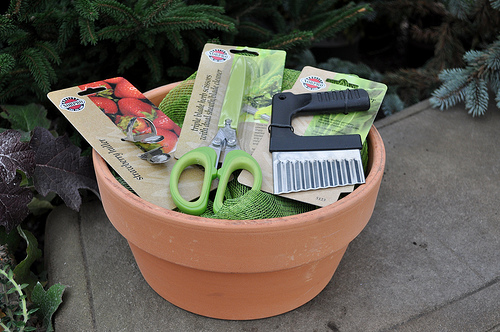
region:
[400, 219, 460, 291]
A gray concrete bench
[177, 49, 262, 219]
New green pruning shears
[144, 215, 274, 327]
A terracotta planter on bench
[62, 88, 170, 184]
A pack of strawberry seeds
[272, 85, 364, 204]
A black handled garden tool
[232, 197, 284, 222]
A piece of green garden mesh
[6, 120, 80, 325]
Purple and green plants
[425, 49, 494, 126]
A green plant branch on bench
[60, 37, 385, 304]
A pot full of gardening tools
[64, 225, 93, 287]
Dark line on concrete bench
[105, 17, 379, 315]
pot filled with kitchen items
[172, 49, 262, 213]
brand new green scissors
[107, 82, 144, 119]
strawberries on cardboard packaging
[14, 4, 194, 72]
green pine trees behind pot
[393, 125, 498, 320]
grey cement bench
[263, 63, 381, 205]
kitchen tool with black handle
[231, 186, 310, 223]
green plastic netting in pot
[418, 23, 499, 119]
lighter green pine tree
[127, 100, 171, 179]
silver tool to help with strawberries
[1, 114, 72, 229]
large reddish leaves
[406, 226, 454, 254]
small spot on asphalt bench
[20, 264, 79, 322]
green leaf on side of bench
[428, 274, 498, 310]
line on asphalt bench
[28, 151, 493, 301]
large gray asphalt bench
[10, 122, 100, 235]
purple leaf with lines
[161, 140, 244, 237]
green handle of green scissors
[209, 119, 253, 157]
silver screws on scissors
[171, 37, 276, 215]
large green scissors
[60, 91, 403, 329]
red clay pot on bench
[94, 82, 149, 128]
picture of strawberry on cardboard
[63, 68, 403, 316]
red clay garden pot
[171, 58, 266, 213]
green scissors in their package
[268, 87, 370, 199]
black and silver garden tool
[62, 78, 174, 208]
new strawberry picking tool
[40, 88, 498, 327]
cement pad where clay pot is sitting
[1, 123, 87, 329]
plant on left lower side of painting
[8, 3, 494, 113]
pine branches in upper portion of picture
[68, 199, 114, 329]
seam in cement on left side of picture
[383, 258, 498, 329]
seam in lower right section of cement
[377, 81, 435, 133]
seam in upper right section of cement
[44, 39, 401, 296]
new gardening products in a terra cotta bowl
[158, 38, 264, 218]
scissors new in package for gardening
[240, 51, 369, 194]
scraper or vegetable cutter new in package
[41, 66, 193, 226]
strawberry huller - removes top from strawberries new in package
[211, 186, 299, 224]
green netting may contain flower bulbs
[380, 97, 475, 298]
cement style wall or sidewalk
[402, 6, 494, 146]
blue spruce pine branch on sdewakl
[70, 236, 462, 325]
bottom of terra cotta bowl on cement surface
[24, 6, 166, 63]
pine branches in the background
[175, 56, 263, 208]
scissors with light green handle